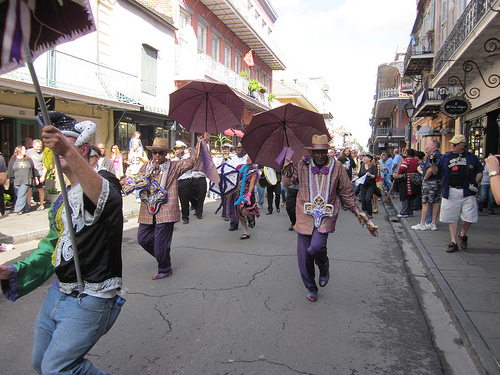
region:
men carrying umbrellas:
[144, 63, 339, 200]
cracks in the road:
[174, 244, 289, 371]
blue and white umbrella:
[210, 163, 249, 217]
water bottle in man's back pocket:
[104, 273, 169, 333]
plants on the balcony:
[248, 73, 275, 107]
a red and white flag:
[235, 47, 263, 71]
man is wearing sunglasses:
[142, 134, 189, 171]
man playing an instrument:
[108, 136, 199, 229]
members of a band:
[167, 140, 237, 171]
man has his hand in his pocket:
[408, 147, 440, 199]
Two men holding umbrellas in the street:
[132, 77, 355, 299]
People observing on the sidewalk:
[370, 122, 497, 266]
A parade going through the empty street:
[29, 105, 445, 369]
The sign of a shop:
[435, 92, 475, 120]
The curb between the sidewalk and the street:
[390, 251, 495, 366]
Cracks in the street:
[187, 236, 279, 323]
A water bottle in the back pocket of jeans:
[110, 280, 135, 314]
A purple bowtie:
[307, 164, 329, 174]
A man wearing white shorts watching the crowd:
[430, 132, 476, 248]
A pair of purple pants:
[290, 225, 340, 300]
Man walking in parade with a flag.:
[0, 0, 121, 373]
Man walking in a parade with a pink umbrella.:
[240, 102, 384, 310]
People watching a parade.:
[380, 121, 483, 257]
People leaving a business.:
[2, 127, 48, 212]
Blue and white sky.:
[272, 0, 377, 86]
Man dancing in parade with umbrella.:
[130, 78, 244, 284]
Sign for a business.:
[440, 93, 472, 119]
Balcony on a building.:
[375, 65, 400, 100]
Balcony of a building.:
[371, 108, 410, 137]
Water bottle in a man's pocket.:
[102, 276, 132, 333]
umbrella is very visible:
[170, 85, 446, 324]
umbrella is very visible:
[237, 111, 340, 203]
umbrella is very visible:
[210, 95, 332, 262]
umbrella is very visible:
[232, 77, 399, 276]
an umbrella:
[217, 112, 346, 238]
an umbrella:
[220, 93, 296, 188]